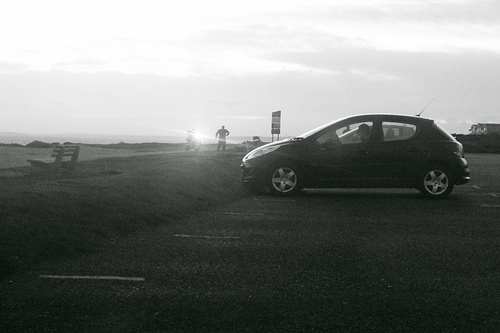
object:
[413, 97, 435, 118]
antennae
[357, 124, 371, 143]
someone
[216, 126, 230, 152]
man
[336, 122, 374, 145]
window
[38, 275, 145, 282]
line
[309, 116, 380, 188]
side door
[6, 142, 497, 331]
ground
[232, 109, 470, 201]
fronttire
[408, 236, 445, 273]
patch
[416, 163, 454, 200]
back tire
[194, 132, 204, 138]
sun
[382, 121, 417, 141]
window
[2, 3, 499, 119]
sky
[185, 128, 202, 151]
glare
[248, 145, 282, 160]
headlight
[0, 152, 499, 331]
asphalt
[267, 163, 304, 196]
tire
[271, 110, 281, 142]
sign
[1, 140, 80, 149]
mountains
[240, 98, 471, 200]
car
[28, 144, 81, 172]
bench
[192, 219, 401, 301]
road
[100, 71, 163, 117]
part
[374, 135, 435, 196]
door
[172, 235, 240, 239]
paint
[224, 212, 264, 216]
paint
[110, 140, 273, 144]
horizon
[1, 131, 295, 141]
water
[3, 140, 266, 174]
beach